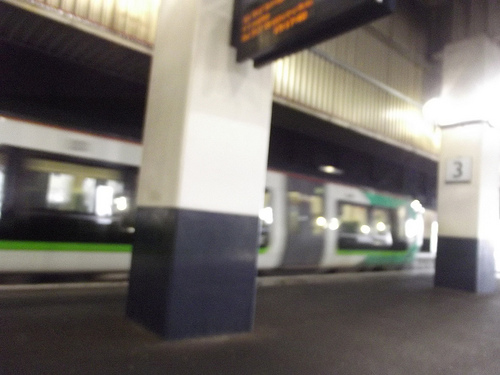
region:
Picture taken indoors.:
[12, 11, 471, 355]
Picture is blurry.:
[22, 37, 427, 349]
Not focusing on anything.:
[22, 31, 485, 363]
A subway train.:
[41, 126, 396, 281]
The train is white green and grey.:
[25, 131, 390, 303]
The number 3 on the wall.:
[419, 122, 492, 239]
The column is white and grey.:
[147, 72, 267, 296]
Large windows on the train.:
[30, 147, 424, 267]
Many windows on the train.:
[9, 122, 351, 279]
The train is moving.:
[49, 145, 429, 311]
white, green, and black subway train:
[22, 46, 447, 327]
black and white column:
[138, 64, 294, 360]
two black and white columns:
[152, 76, 494, 342]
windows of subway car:
[333, 203, 411, 267]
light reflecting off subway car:
[317, 191, 437, 266]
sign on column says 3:
[436, 146, 474, 199]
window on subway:
[18, 146, 151, 238]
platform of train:
[29, 250, 474, 335]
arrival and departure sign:
[229, 5, 414, 60]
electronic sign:
[226, 8, 419, 75]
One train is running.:
[22, 121, 437, 296]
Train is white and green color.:
[8, 117, 435, 299]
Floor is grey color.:
[310, 298, 434, 368]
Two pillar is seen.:
[149, 134, 499, 286]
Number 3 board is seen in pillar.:
[438, 153, 470, 193]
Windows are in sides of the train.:
[1, 153, 412, 281]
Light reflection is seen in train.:
[30, 157, 433, 267]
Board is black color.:
[221, 4, 401, 69]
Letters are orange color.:
[218, 0, 374, 56]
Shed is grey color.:
[323, 58, 443, 109]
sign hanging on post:
[222, 10, 377, 57]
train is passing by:
[12, 130, 439, 277]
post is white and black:
[127, 2, 262, 329]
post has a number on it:
[439, 23, 496, 317]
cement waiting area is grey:
[289, 275, 449, 366]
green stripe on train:
[0, 227, 275, 263]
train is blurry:
[0, 114, 430, 269]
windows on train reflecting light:
[15, 137, 412, 261]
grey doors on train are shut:
[286, 174, 331, 276]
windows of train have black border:
[334, 195, 409, 258]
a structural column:
[106, 5, 296, 349]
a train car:
[257, 166, 438, 280]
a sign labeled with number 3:
[442, 152, 474, 187]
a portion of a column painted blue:
[116, 199, 282, 341]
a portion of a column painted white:
[135, 0, 275, 220]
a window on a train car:
[0, 160, 141, 250]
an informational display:
[233, 0, 404, 70]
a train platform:
[1, 267, 481, 370]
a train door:
[280, 169, 341, 281]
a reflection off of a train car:
[398, 190, 433, 274]